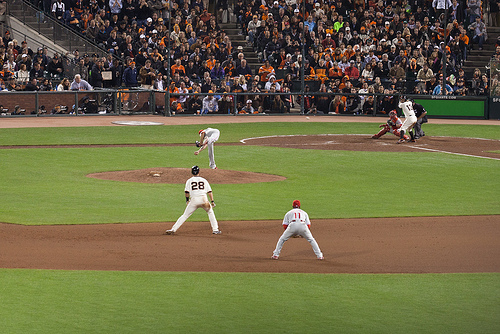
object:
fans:
[137, 57, 160, 90]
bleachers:
[457, 29, 471, 64]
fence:
[0, 88, 499, 118]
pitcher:
[194, 126, 220, 170]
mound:
[87, 165, 287, 185]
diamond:
[0, 143, 500, 226]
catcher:
[372, 110, 410, 142]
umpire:
[408, 98, 427, 139]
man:
[270, 200, 326, 260]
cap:
[291, 200, 301, 207]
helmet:
[191, 165, 200, 176]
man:
[166, 165, 221, 235]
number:
[294, 211, 301, 220]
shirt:
[283, 208, 311, 224]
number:
[190, 180, 205, 191]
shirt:
[185, 176, 212, 199]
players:
[395, 95, 419, 144]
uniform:
[170, 175, 221, 230]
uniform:
[274, 209, 322, 259]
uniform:
[203, 127, 221, 165]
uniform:
[400, 100, 417, 138]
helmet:
[388, 108, 399, 119]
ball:
[304, 115, 311, 120]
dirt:
[0, 216, 499, 273]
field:
[0, 114, 500, 333]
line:
[411, 144, 500, 164]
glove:
[195, 141, 202, 147]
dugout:
[0, 91, 167, 116]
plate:
[373, 138, 389, 149]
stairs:
[55, 38, 88, 47]